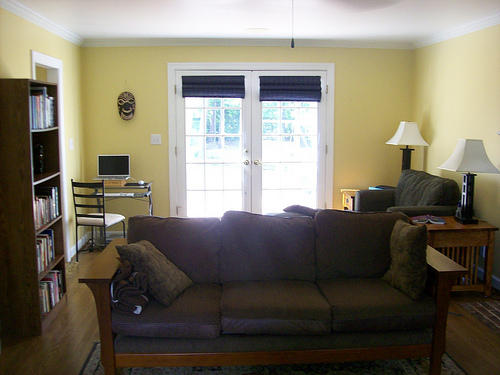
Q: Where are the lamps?
A: Against the right wall.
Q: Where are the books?
A: On the brown shelf.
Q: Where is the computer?
A: In the upper left corner.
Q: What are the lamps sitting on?
A: Wooden end tables.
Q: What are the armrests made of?
A: Wood.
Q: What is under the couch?
A: Rug.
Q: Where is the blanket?
A: Under the pillow.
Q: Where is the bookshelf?
A: Against the wall.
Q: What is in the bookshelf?
A: Books.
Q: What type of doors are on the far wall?
A: French doors.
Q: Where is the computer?
A: On the desk.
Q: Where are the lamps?
A: On either side of the chair on the right wall.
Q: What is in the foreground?
A: A sofa.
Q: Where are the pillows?
A: On the sofa.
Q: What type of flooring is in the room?
A: Wooden.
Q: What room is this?
A: Living room.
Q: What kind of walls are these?
A: Yellow walls.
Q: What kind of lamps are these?
A: Black lamps.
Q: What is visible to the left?
A: A bookshelf.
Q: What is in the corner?
A: A desk.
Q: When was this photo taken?
A: It is Day.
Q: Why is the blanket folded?
A: To be Neat.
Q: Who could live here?
A: A family.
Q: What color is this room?
A: Yellow.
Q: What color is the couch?
A: Brown.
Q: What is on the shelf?
A: Books.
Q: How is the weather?
A: It is sunny.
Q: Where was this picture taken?
A: Living Room.